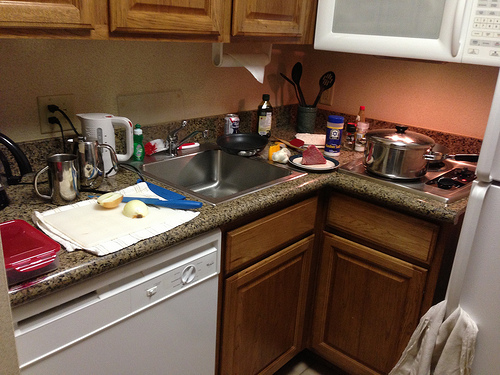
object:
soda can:
[224, 113, 240, 136]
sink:
[120, 141, 308, 207]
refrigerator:
[428, 73, 498, 375]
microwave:
[312, 0, 499, 68]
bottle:
[131, 123, 145, 161]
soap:
[133, 123, 145, 160]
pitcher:
[75, 111, 137, 178]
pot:
[360, 120, 479, 184]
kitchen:
[0, 0, 499, 371]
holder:
[210, 39, 275, 69]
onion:
[98, 192, 124, 209]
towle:
[29, 181, 202, 256]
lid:
[0, 218, 63, 271]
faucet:
[167, 116, 208, 155]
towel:
[383, 301, 481, 375]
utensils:
[278, 71, 301, 107]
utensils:
[291, 61, 307, 107]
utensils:
[311, 69, 336, 107]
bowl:
[0, 218, 62, 287]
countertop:
[0, 120, 477, 288]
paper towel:
[212, 51, 269, 86]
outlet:
[38, 93, 78, 134]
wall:
[0, 37, 300, 143]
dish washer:
[10, 227, 222, 374]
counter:
[0, 119, 484, 311]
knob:
[395, 123, 409, 134]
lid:
[362, 121, 437, 151]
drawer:
[325, 194, 443, 264]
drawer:
[221, 190, 322, 275]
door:
[308, 229, 428, 374]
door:
[220, 234, 316, 375]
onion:
[121, 198, 150, 219]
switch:
[145, 286, 158, 298]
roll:
[213, 52, 269, 67]